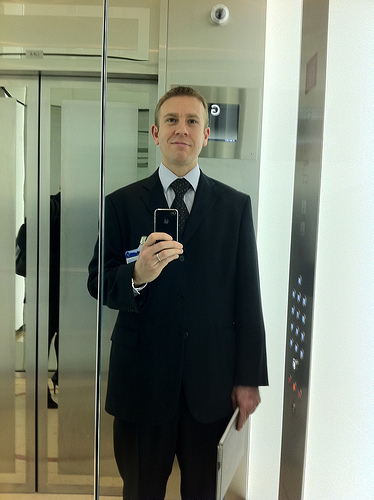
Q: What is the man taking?
A: A selfie.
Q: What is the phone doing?
A: Taking a picture.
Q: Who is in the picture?
A: A man.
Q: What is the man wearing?
A: A suit.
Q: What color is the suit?
A: Black.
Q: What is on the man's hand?
A: A ring.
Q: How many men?
A: One.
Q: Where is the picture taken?
A: Near mirror.